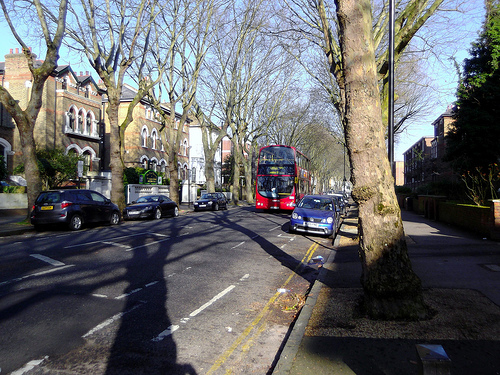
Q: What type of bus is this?
A: Double decker.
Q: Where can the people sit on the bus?
A: On two levels.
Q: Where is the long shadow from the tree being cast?
A: Across the street.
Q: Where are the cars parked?
A: On the sides of the street.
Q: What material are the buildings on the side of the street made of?
A: Brick.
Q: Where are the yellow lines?
A: On the street.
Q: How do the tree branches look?
A: Bare.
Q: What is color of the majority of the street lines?
A: White.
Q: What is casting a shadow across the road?
A: Tree.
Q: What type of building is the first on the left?
A: Multi story brick.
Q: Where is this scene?
A: Neighborhood.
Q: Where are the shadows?
A: Street.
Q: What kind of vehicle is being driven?
A: Double decker bus.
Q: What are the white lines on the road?
A: Traffic lines.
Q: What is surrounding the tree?
A: Gravel.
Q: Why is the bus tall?
A: It's a double decker bus.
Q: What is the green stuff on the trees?
A: Moss.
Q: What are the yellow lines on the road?
A: Parking.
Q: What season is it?
A: Autumn.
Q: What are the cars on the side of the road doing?
A: They're parked.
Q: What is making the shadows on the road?
A: Trees.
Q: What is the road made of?
A: Pavement.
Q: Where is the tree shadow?
A: On the road.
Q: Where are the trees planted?
A: On the sidewalk.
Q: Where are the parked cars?
A: On the street.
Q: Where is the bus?
A: On the roadway.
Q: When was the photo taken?
A: Daytime.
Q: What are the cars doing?
A: Parked.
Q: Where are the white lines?
A: Street.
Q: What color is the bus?
A: Red.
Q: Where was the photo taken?
A: On a tree-lined street.